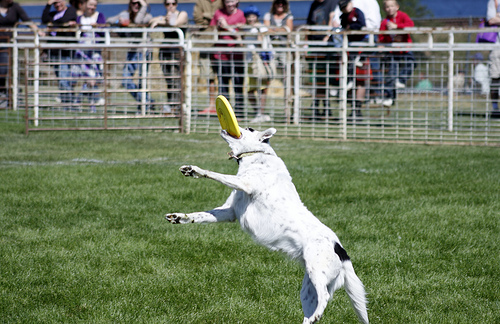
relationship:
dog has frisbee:
[165, 126, 371, 323] [213, 92, 241, 138]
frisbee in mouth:
[213, 92, 241, 138] [220, 128, 249, 143]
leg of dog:
[179, 164, 258, 195] [165, 126, 371, 323]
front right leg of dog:
[165, 211, 248, 224] [165, 126, 371, 323]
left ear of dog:
[256, 125, 280, 142] [165, 126, 371, 323]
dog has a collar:
[165, 126, 371, 323] [228, 153, 280, 162]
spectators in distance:
[1, 0, 497, 120] [1, 0, 499, 148]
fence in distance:
[0, 28, 498, 133] [1, 0, 499, 148]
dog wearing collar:
[165, 126, 371, 323] [228, 153, 280, 162]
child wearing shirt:
[379, 2, 417, 109] [376, 10, 413, 54]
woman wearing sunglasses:
[153, 1, 190, 120] [165, 1, 178, 9]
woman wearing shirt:
[211, 0, 248, 125] [209, 11, 245, 60]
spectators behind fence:
[1, 0, 497, 120] [0, 28, 498, 133]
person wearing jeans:
[42, 1, 78, 107] [50, 52, 76, 107]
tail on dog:
[331, 234, 377, 324] [165, 126, 371, 323]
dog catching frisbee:
[165, 126, 371, 323] [213, 92, 241, 138]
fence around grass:
[0, 28, 498, 133] [3, 143, 498, 321]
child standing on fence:
[379, 2, 417, 109] [0, 28, 498, 133]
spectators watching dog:
[1, 0, 497, 120] [165, 126, 371, 323]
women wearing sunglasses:
[115, 0, 193, 117] [130, 1, 178, 7]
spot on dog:
[332, 240, 351, 266] [165, 126, 371, 323]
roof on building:
[1, 0, 487, 27] [3, 20, 488, 96]